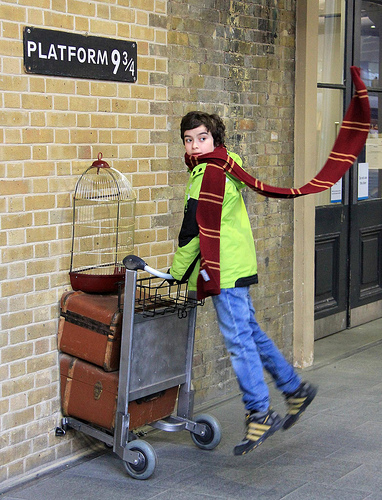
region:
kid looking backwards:
[138, 81, 284, 261]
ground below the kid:
[258, 446, 319, 487]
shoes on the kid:
[221, 387, 330, 464]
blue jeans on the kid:
[212, 305, 295, 389]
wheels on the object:
[107, 415, 225, 489]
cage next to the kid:
[49, 144, 145, 279]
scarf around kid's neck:
[167, 144, 246, 206]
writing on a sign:
[16, 22, 160, 90]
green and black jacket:
[181, 168, 249, 239]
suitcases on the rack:
[68, 292, 116, 417]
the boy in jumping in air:
[176, 102, 321, 460]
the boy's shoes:
[232, 380, 320, 458]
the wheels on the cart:
[127, 418, 223, 480]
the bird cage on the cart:
[71, 151, 135, 287]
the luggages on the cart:
[56, 288, 138, 430]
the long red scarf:
[181, 61, 374, 302]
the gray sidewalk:
[213, 450, 331, 498]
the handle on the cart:
[122, 253, 188, 286]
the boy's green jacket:
[162, 150, 260, 289]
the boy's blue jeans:
[207, 276, 301, 411]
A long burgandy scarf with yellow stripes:
[181, 65, 372, 261]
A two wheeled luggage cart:
[55, 260, 223, 483]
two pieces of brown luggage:
[47, 290, 188, 432]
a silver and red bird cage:
[59, 151, 149, 305]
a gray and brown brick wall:
[179, 12, 289, 108]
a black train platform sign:
[9, 17, 157, 105]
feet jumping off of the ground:
[201, 319, 350, 483]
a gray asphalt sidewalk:
[310, 423, 375, 489]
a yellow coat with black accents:
[151, 150, 293, 311]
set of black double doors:
[317, 90, 379, 354]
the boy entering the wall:
[66, 104, 318, 471]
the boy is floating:
[163, 102, 332, 465]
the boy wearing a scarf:
[157, 124, 300, 295]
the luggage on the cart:
[53, 266, 227, 473]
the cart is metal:
[95, 241, 244, 490]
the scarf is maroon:
[184, 143, 354, 301]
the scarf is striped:
[185, 148, 356, 280]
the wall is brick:
[7, 94, 140, 152]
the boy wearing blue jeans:
[180, 253, 323, 434]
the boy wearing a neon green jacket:
[144, 141, 259, 296]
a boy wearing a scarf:
[58, 53, 381, 372]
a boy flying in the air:
[56, 35, 377, 361]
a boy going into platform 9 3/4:
[9, 10, 379, 348]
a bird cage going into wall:
[17, 109, 183, 296]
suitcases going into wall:
[36, 182, 278, 489]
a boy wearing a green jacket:
[137, 68, 371, 320]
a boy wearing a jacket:
[119, 81, 380, 402]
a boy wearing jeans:
[150, 87, 330, 368]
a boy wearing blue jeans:
[91, 97, 380, 428]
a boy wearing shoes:
[142, 73, 343, 425]